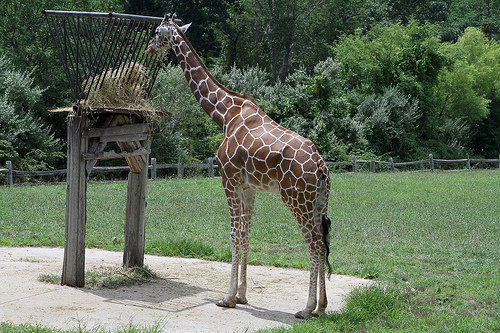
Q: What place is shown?
A: It is a meadow.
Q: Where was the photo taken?
A: It was taken at the meadow.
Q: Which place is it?
A: It is a meadow.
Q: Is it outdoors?
A: Yes, it is outdoors.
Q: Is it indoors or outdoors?
A: It is outdoors.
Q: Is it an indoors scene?
A: No, it is outdoors.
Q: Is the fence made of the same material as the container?
A: No, the fence is made of wood and the container is made of metal.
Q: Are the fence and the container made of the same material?
A: No, the fence is made of wood and the container is made of metal.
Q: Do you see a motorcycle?
A: No, there are no motorcycles.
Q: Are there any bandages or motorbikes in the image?
A: No, there are no motorbikes or bandages.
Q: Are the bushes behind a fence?
A: Yes, the bushes are behind a fence.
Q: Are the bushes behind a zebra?
A: No, the bushes are behind a fence.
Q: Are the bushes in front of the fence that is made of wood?
A: No, the bushes are behind the fence.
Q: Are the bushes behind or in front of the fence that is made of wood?
A: The bushes are behind the fence.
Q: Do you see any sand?
A: Yes, there is sand.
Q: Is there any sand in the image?
A: Yes, there is sand.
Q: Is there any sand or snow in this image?
A: Yes, there is sand.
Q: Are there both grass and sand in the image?
A: Yes, there are both sand and grass.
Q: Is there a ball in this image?
A: No, there are no balls.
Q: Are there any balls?
A: No, there are no balls.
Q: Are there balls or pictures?
A: No, there are no balls or pictures.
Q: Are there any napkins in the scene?
A: No, there are no napkins.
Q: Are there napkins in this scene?
A: No, there are no napkins.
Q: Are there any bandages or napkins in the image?
A: No, there are no napkins or bandages.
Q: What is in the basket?
A: The hay is in the basket.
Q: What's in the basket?
A: The hay is in the basket.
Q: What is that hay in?
A: The hay is in the basket.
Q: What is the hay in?
A: The hay is in the basket.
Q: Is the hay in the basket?
A: Yes, the hay is in the basket.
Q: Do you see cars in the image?
A: No, there are no cars.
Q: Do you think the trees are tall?
A: Yes, the trees are tall.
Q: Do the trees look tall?
A: Yes, the trees are tall.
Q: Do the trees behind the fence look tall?
A: Yes, the trees are tall.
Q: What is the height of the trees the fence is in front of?
A: The trees are tall.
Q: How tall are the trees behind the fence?
A: The trees are tall.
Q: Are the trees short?
A: No, the trees are tall.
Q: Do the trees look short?
A: No, the trees are tall.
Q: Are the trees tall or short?
A: The trees are tall.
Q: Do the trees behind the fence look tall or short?
A: The trees are tall.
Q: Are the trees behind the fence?
A: Yes, the trees are behind the fence.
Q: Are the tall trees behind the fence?
A: Yes, the trees are behind the fence.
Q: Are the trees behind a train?
A: No, the trees are behind the fence.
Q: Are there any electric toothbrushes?
A: No, there are no electric toothbrushes.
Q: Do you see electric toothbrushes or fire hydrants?
A: No, there are no electric toothbrushes or fire hydrants.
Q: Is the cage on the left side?
A: Yes, the cage is on the left of the image.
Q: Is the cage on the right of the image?
A: No, the cage is on the left of the image.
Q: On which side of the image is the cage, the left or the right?
A: The cage is on the left of the image.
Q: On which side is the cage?
A: The cage is on the left of the image.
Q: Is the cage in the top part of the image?
A: Yes, the cage is in the top of the image.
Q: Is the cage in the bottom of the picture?
A: No, the cage is in the top of the image.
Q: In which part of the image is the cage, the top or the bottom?
A: The cage is in the top of the image.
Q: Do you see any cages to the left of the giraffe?
A: Yes, there is a cage to the left of the giraffe.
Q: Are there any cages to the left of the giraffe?
A: Yes, there is a cage to the left of the giraffe.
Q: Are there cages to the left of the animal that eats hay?
A: Yes, there is a cage to the left of the giraffe.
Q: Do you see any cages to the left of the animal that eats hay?
A: Yes, there is a cage to the left of the giraffe.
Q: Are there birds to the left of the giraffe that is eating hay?
A: No, there is a cage to the left of the giraffe.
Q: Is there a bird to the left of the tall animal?
A: No, there is a cage to the left of the giraffe.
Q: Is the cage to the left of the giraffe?
A: Yes, the cage is to the left of the giraffe.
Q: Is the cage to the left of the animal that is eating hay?
A: Yes, the cage is to the left of the giraffe.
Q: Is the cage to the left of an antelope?
A: No, the cage is to the left of the giraffe.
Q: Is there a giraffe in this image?
A: Yes, there is a giraffe.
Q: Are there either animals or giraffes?
A: Yes, there is a giraffe.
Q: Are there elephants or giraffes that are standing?
A: Yes, the giraffe is standing.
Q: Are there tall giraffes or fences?
A: Yes, there is a tall giraffe.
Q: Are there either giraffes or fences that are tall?
A: Yes, the giraffe is tall.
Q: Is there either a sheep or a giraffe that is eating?
A: Yes, the giraffe is eating.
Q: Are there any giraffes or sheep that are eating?
A: Yes, the giraffe is eating.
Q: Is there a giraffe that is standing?
A: Yes, there is a giraffe that is standing.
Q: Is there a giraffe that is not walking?
A: Yes, there is a giraffe that is standing.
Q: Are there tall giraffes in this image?
A: Yes, there is a tall giraffe.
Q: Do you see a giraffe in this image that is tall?
A: Yes, there is a giraffe that is tall.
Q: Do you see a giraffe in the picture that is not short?
A: Yes, there is a tall giraffe.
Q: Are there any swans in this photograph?
A: No, there are no swans.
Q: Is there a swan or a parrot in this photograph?
A: No, there are no swans or parrots.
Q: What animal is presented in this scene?
A: The animal is a giraffe.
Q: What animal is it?
A: The animal is a giraffe.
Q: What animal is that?
A: That is a giraffe.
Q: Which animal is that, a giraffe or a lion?
A: That is a giraffe.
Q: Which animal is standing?
A: The animal is a giraffe.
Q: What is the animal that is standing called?
A: The animal is a giraffe.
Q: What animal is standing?
A: The animal is a giraffe.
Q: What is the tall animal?
A: The animal is a giraffe.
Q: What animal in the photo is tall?
A: The animal is a giraffe.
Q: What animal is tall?
A: The animal is a giraffe.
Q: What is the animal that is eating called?
A: The animal is a giraffe.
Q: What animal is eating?
A: The animal is a giraffe.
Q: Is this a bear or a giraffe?
A: This is a giraffe.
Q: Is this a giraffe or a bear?
A: This is a giraffe.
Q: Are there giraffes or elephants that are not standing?
A: No, there is a giraffe but it is standing.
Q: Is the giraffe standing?
A: Yes, the giraffe is standing.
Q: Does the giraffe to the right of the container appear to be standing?
A: Yes, the giraffe is standing.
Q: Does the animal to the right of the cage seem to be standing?
A: Yes, the giraffe is standing.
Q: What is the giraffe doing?
A: The giraffe is standing.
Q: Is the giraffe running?
A: No, the giraffe is standing.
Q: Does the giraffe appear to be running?
A: No, the giraffe is standing.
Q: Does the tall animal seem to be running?
A: No, the giraffe is standing.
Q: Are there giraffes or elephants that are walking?
A: No, there is a giraffe but it is standing.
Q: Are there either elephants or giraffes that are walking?
A: No, there is a giraffe but it is standing.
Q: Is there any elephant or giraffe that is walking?
A: No, there is a giraffe but it is standing.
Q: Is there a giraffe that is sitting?
A: No, there is a giraffe but it is standing.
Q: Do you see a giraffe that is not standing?
A: No, there is a giraffe but it is standing.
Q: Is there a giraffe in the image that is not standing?
A: No, there is a giraffe but it is standing.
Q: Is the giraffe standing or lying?
A: The giraffe is standing.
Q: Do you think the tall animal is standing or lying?
A: The giraffe is standing.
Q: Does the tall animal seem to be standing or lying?
A: The giraffe is standing.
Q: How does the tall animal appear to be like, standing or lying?
A: The giraffe is standing.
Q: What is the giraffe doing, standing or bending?
A: The giraffe is standing.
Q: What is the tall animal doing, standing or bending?
A: The giraffe is standing.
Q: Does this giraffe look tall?
A: Yes, the giraffe is tall.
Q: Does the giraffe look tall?
A: Yes, the giraffe is tall.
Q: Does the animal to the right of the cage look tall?
A: Yes, the giraffe is tall.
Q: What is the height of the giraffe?
A: The giraffe is tall.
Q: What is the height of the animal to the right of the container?
A: The giraffe is tall.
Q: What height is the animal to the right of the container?
A: The giraffe is tall.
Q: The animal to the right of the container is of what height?
A: The giraffe is tall.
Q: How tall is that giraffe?
A: The giraffe is tall.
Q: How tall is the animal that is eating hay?
A: The giraffe is tall.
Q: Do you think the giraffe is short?
A: No, the giraffe is tall.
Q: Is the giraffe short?
A: No, the giraffe is tall.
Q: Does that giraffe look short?
A: No, the giraffe is tall.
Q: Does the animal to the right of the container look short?
A: No, the giraffe is tall.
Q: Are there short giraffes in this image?
A: No, there is a giraffe but it is tall.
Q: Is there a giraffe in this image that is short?
A: No, there is a giraffe but it is tall.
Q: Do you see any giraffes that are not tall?
A: No, there is a giraffe but it is tall.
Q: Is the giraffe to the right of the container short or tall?
A: The giraffe is tall.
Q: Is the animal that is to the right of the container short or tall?
A: The giraffe is tall.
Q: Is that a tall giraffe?
A: Yes, that is a tall giraffe.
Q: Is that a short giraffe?
A: No, that is a tall giraffe.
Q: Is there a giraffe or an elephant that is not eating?
A: No, there is a giraffe but it is eating.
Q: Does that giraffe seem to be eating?
A: Yes, the giraffe is eating.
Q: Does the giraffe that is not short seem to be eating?
A: Yes, the giraffe is eating.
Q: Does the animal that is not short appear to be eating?
A: Yes, the giraffe is eating.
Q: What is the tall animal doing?
A: The giraffe is eating.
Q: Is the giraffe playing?
A: No, the giraffe is eating.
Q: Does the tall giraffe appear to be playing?
A: No, the giraffe is eating.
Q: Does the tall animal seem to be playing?
A: No, the giraffe is eating.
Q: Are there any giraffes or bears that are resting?
A: No, there is a giraffe but it is eating.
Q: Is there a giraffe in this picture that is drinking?
A: No, there is a giraffe but it is eating.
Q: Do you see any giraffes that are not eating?
A: No, there is a giraffe but it is eating.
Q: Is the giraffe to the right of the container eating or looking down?
A: The giraffe is eating.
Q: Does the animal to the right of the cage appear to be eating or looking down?
A: The giraffe is eating.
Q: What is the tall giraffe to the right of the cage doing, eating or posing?
A: The giraffe is eating.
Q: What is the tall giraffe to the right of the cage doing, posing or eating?
A: The giraffe is eating.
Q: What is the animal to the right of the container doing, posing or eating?
A: The giraffe is eating.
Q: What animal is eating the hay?
A: The giraffe is eating the hay.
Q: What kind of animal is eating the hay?
A: The animal is a giraffe.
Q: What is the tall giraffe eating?
A: The giraffe is eating hay.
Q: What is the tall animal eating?
A: The giraffe is eating hay.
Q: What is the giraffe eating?
A: The giraffe is eating hay.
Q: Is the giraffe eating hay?
A: Yes, the giraffe is eating hay.